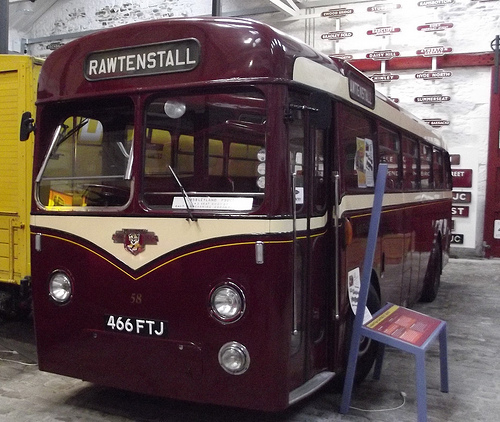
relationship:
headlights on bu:
[44, 264, 255, 378] [17, 12, 463, 414]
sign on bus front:
[83, 36, 200, 73] [30, 22, 284, 405]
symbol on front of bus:
[111, 227, 159, 256] [32, 17, 486, 416]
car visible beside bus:
[0, 52, 257, 286] [32, 17, 486, 416]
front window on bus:
[139, 84, 269, 214] [32, 17, 486, 416]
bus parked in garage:
[32, 17, 486, 416] [3, 0, 490, 417]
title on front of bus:
[87, 46, 196, 75] [72, 51, 357, 327]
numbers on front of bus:
[105, 314, 135, 330] [40, 25, 310, 385]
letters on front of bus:
[134, 318, 164, 336] [40, 25, 310, 385]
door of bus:
[283, 89, 338, 391] [32, 17, 486, 416]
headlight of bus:
[46, 264, 73, 308] [32, 17, 486, 416]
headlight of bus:
[203, 277, 250, 328] [32, 17, 486, 416]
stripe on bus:
[30, 188, 454, 270] [32, 17, 486, 416]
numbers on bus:
[103, 312, 135, 333] [32, 17, 486, 416]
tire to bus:
[429, 226, 449, 301] [32, 17, 486, 416]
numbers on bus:
[102, 312, 174, 337] [32, 17, 486, 416]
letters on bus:
[85, 47, 205, 76] [32, 17, 486, 416]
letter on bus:
[152, 317, 167, 338] [32, 17, 486, 416]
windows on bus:
[429, 148, 449, 187] [32, 17, 486, 416]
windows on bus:
[416, 141, 438, 186] [32, 17, 486, 416]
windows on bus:
[400, 134, 425, 188] [32, 17, 486, 416]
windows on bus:
[376, 124, 416, 191] [32, 17, 486, 416]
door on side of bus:
[283, 89, 335, 391] [32, 17, 486, 416]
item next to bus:
[351, 298, 458, 403] [32, 17, 486, 416]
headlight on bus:
[205, 278, 246, 323] [32, 17, 486, 416]